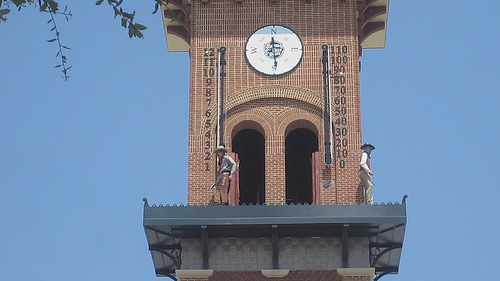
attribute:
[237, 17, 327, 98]
clock — large 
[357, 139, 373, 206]
cowboy — standing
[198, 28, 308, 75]
wall — brick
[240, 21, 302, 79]
clock — white, brwon 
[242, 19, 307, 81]
compass — large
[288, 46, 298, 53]
e — large 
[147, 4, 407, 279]
tower — brown 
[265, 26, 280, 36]
n — black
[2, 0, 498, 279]
sky — clear, blue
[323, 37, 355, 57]
wall — brick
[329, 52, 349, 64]
number 100 — black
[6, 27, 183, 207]
sky — clear, blue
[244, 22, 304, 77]
compass — black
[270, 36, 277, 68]
hand — long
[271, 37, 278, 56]
hand — black 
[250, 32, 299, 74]
number — black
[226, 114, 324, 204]
archways — dark